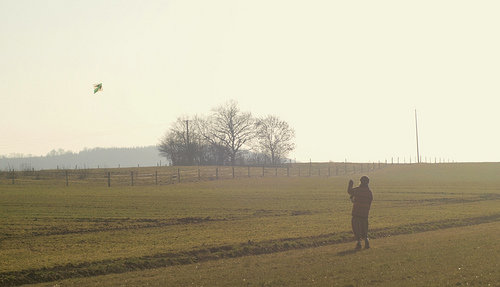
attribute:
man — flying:
[333, 161, 390, 258]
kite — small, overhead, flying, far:
[81, 73, 119, 111]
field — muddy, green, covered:
[3, 163, 498, 283]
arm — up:
[341, 171, 360, 211]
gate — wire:
[29, 159, 477, 171]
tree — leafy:
[140, 98, 304, 168]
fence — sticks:
[15, 149, 480, 173]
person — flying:
[317, 155, 395, 252]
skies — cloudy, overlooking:
[3, 4, 500, 193]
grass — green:
[21, 174, 490, 275]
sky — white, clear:
[3, 4, 498, 171]